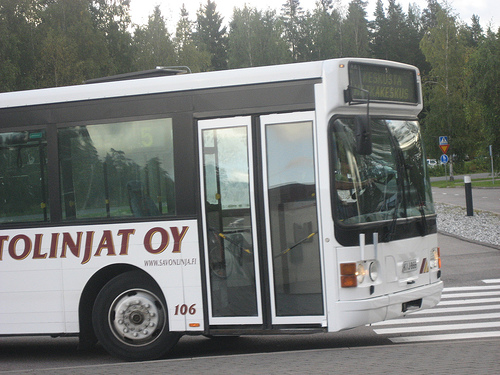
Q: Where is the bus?
A: On the street.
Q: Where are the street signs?
A: Behind the bus.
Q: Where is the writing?
A: Bus.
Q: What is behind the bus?
A: Trees.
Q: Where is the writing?
A: Side of the bus.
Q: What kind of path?
A: Bike.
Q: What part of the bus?
A: Windshield.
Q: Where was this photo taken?
A: On a road.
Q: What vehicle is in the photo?
A: A bus.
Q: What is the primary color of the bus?
A: White.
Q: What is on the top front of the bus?
A: A digital screen.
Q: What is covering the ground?
A: Pavement.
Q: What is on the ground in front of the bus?
A: White lines.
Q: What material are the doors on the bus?
A: Glass.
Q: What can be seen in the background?
A: Trees.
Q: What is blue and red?
A: Signs.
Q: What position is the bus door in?
A: Closed.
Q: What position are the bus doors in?
A: Closed.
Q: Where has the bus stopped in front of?
A: A cross walk.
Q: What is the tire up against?
A: A curb.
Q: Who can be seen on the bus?
A: Nobody can bee seen.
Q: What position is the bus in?
A: Parked.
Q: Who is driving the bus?
A: Bus driver.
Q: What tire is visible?
A: Right passenger side.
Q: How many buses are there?
A: One.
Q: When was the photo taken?
A: Day time.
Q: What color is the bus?
A: White.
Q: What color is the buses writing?
A: Red.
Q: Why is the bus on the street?
A: Driving.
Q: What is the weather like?
A: Cloudy.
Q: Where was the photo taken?
A: On a street.